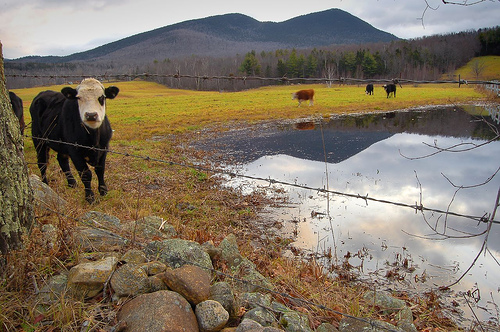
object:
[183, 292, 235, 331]
rocks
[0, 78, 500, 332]
ground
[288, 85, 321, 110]
cow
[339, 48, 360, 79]
trees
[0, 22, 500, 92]
woods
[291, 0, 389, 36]
peak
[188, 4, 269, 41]
peak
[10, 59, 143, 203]
cow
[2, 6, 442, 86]
hills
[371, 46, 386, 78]
trees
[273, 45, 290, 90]
trees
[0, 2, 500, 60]
sky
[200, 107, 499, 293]
reflection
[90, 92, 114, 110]
black eye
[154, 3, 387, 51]
ridge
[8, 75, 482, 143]
grass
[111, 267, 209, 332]
rocks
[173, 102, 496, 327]
pond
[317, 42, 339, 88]
trees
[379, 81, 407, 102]
cow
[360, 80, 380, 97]
cow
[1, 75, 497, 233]
pasture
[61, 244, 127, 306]
rocks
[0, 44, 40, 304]
tree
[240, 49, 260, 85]
tree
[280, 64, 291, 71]
leaves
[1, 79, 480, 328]
grass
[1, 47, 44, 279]
bark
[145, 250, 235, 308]
boulders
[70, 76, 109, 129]
face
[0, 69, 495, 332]
fence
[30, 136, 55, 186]
legs